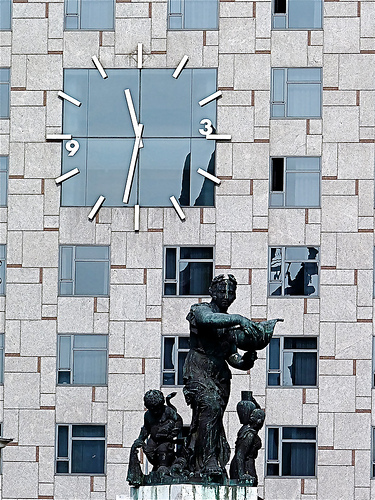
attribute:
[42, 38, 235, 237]
clock — modern, fancy, large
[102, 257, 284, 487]
statue — part of a fountain, postmodern, above tower, woman, boy, portait, portrait, seated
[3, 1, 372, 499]
hotel — large, white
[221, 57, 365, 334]
walls — mosaic, sketched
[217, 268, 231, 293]
stain — white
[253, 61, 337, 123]
window — white